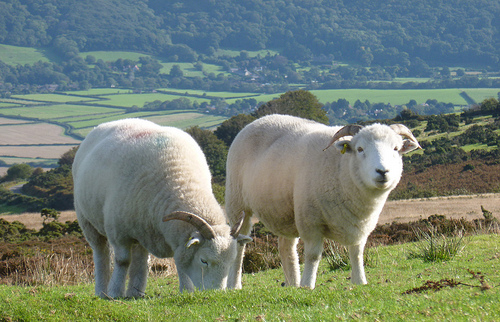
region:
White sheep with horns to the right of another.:
[223, 110, 421, 287]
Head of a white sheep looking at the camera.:
[351, 122, 404, 187]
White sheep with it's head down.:
[70, 116, 252, 298]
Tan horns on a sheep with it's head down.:
[159, 208, 251, 239]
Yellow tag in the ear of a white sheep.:
[338, 140, 348, 155]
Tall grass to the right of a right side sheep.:
[406, 218, 468, 261]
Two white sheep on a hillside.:
[71, 113, 421, 303]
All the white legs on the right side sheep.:
[224, 201, 369, 290]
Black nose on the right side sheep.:
[374, 167, 391, 174]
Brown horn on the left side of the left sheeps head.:
[162, 210, 216, 240]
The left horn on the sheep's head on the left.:
[165, 210, 215, 239]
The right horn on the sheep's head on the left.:
[229, 213, 252, 233]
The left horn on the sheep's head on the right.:
[327, 128, 362, 136]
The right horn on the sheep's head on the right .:
[399, 125, 420, 142]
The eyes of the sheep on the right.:
[355, 143, 405, 153]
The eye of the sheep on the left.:
[195, 252, 207, 264]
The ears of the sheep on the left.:
[183, 233, 253, 250]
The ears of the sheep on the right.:
[338, 131, 419, 156]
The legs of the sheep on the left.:
[87, 240, 152, 298]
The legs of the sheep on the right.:
[242, 219, 376, 289]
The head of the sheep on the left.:
[167, 203, 257, 302]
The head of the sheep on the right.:
[339, 117, 416, 197]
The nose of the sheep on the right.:
[374, 163, 389, 177]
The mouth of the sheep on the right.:
[377, 175, 396, 189]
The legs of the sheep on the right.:
[228, 205, 373, 287]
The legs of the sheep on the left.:
[74, 220, 159, 310]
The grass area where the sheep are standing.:
[39, 258, 430, 320]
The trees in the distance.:
[12, 2, 494, 62]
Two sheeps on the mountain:
[56, 100, 429, 305]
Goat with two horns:
[321, 104, 421, 188]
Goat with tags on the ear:
[329, 134, 355, 161]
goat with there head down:
[162, 223, 262, 305]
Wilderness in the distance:
[139, 17, 356, 112]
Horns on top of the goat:
[158, 181, 260, 263]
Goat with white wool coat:
[229, 98, 349, 237]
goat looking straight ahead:
[333, 115, 413, 210]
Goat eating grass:
[56, 110, 245, 297]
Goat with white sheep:
[225, 168, 369, 240]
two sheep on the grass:
[72, 114, 420, 299]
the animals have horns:
[165, 118, 422, 244]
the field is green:
[0, 0, 498, 320]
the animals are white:
[77, 114, 419, 286]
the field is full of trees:
[0, 1, 497, 319]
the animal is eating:
[68, 115, 245, 292]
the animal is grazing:
[71, 120, 248, 297]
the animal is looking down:
[69, 118, 251, 296]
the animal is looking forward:
[221, 113, 418, 285]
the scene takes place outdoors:
[0, 5, 498, 320]